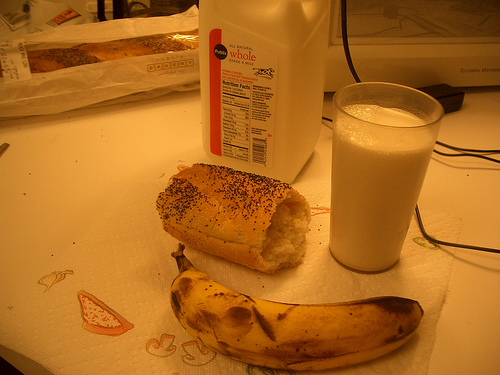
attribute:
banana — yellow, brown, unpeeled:
[168, 244, 424, 373]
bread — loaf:
[29, 30, 201, 75]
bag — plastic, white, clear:
[1, 4, 201, 121]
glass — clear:
[328, 80, 445, 273]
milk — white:
[331, 104, 433, 271]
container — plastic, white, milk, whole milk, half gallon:
[199, 1, 330, 186]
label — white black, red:
[206, 27, 279, 170]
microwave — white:
[324, 1, 500, 91]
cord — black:
[341, 1, 361, 84]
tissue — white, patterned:
[1, 158, 464, 374]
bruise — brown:
[250, 303, 277, 342]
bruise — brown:
[224, 306, 253, 337]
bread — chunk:
[155, 163, 311, 276]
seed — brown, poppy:
[204, 222, 208, 228]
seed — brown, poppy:
[214, 217, 219, 222]